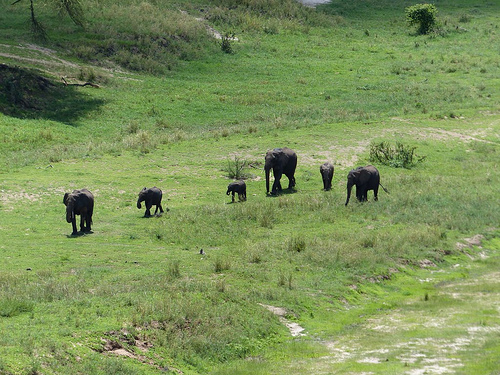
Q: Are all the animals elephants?
A: Yes, all the animals are elephants.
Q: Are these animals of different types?
A: No, all the animals are elephants.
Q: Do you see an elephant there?
A: Yes, there are elephants.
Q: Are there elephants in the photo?
A: Yes, there are elephants.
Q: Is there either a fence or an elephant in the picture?
A: Yes, there are elephants.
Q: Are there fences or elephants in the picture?
A: Yes, there are elephants.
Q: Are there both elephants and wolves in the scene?
A: No, there are elephants but no wolves.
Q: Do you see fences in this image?
A: No, there are no fences.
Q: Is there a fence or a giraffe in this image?
A: No, there are no fences or giraffes.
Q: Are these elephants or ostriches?
A: These are elephants.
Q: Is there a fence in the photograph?
A: No, there are no fences.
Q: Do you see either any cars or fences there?
A: No, there are no fences or cars.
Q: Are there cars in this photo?
A: No, there are no cars.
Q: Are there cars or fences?
A: No, there are no cars or fences.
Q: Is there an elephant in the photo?
A: Yes, there is an elephant.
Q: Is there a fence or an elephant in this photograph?
A: Yes, there is an elephant.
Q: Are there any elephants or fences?
A: Yes, there is an elephant.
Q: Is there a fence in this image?
A: No, there are no fences.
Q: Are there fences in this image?
A: No, there are no fences.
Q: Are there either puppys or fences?
A: No, there are no fences or puppys.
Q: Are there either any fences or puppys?
A: No, there are no fences or puppys.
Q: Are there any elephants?
A: Yes, there is an elephant.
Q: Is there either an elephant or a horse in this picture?
A: Yes, there is an elephant.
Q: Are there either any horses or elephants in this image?
A: Yes, there is an elephant.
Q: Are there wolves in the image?
A: No, there are no wolves.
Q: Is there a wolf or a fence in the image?
A: No, there are no wolves or fences.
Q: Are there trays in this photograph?
A: No, there are no trays.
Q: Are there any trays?
A: No, there are no trays.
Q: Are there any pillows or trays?
A: No, there are no trays or pillows.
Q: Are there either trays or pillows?
A: No, there are no trays or pillows.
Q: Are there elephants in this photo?
A: Yes, there is an elephant.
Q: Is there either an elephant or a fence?
A: Yes, there is an elephant.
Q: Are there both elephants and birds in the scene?
A: No, there is an elephant but no birds.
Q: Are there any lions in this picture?
A: No, there are no lions.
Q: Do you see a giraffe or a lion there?
A: No, there are no lions or giraffes.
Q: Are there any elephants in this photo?
A: Yes, there is an elephant.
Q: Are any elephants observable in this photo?
A: Yes, there is an elephant.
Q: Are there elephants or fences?
A: Yes, there is an elephant.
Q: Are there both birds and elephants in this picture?
A: No, there is an elephant but no birds.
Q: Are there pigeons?
A: No, there are no pigeons.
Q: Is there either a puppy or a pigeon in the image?
A: No, there are no pigeons or puppies.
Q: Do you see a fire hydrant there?
A: No, there are no fire hydrants.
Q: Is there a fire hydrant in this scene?
A: No, there are no fire hydrants.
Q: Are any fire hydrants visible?
A: No, there are no fire hydrants.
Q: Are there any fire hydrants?
A: No, there are no fire hydrants.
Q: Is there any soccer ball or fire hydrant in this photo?
A: No, there are no fire hydrants or soccer balls.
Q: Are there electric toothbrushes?
A: No, there are no electric toothbrushes.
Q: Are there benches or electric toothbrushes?
A: No, there are no electric toothbrushes or benches.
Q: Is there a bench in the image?
A: No, there are no benches.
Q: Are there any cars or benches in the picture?
A: No, there are no benches or cars.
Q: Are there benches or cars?
A: No, there are no benches or cars.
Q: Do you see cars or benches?
A: No, there are no benches or cars.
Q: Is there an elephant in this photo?
A: Yes, there is an elephant.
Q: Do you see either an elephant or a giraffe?
A: Yes, there is an elephant.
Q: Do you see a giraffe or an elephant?
A: Yes, there is an elephant.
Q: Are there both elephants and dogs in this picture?
A: No, there is an elephant but no dogs.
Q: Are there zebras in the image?
A: No, there are no zebras.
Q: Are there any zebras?
A: No, there are no zebras.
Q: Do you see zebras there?
A: No, there are no zebras.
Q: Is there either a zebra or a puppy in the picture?
A: No, there are no zebras or puppies.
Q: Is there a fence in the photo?
A: No, there are no fences.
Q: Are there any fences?
A: No, there are no fences.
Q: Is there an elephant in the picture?
A: Yes, there is an elephant.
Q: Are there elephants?
A: Yes, there is an elephant.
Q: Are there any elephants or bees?
A: Yes, there is an elephant.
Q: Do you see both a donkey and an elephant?
A: No, there is an elephant but no donkeys.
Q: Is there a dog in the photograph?
A: No, there are no dogs.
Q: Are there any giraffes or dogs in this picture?
A: No, there are no dogs or giraffes.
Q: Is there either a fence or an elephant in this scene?
A: Yes, there is an elephant.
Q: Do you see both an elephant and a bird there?
A: No, there is an elephant but no birds.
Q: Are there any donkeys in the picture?
A: No, there are no donkeys.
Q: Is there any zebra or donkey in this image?
A: No, there are no donkeys or zebras.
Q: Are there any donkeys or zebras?
A: No, there are no donkeys or zebras.